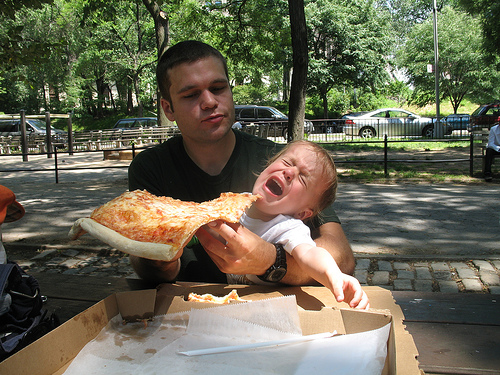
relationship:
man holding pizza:
[128, 41, 357, 288] [76, 187, 259, 262]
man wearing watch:
[128, 41, 357, 288] [257, 243, 288, 285]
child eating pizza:
[201, 141, 367, 311] [76, 187, 259, 262]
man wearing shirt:
[128, 41, 357, 288] [128, 130, 343, 284]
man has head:
[128, 41, 357, 288] [156, 40, 233, 145]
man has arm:
[128, 41, 357, 288] [196, 219, 359, 289]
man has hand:
[128, 41, 357, 288] [194, 221, 266, 277]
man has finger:
[128, 41, 357, 288] [207, 220, 237, 246]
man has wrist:
[128, 41, 357, 288] [253, 237, 269, 279]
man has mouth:
[128, 41, 357, 288] [199, 110, 229, 128]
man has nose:
[128, 41, 357, 288] [199, 87, 217, 112]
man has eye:
[128, 41, 357, 288] [183, 92, 201, 101]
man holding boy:
[128, 41, 357, 288] [201, 141, 367, 311]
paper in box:
[59, 295, 394, 374] [0, 282, 425, 374]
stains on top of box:
[59, 310, 196, 373] [0, 282, 425, 374]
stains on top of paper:
[59, 310, 196, 373] [59, 295, 394, 374]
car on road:
[343, 107, 449, 139] [0, 131, 497, 139]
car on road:
[2, 119, 60, 149] [0, 131, 497, 139]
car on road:
[107, 117, 178, 147] [0, 131, 497, 139]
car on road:
[229, 105, 314, 137] [0, 131, 497, 139]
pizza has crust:
[76, 187, 259, 262] [73, 218, 173, 261]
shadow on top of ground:
[0, 174, 495, 365] [6, 140, 497, 374]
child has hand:
[201, 141, 367, 311] [322, 269, 371, 309]